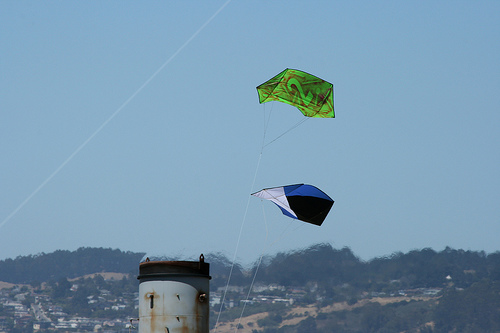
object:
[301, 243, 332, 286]
trees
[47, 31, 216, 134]
sky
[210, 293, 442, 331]
hill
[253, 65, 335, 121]
green kite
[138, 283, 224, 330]
pole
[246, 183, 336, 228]
kite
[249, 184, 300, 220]
white part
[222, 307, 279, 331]
brown grass